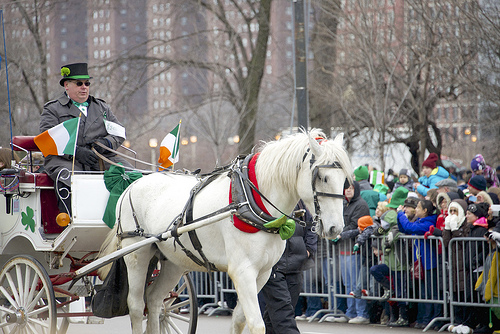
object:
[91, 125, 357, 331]
horse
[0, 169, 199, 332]
white carriage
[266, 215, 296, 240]
bow